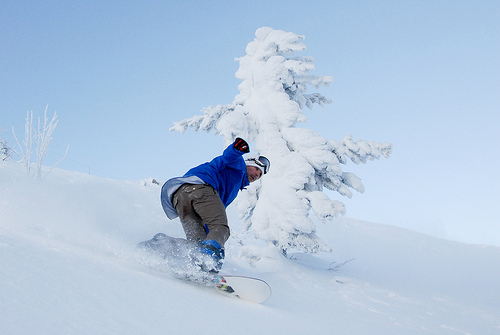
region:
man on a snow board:
[156, 129, 277, 274]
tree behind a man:
[175, 13, 397, 276]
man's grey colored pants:
[166, 178, 233, 253]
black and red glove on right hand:
[231, 133, 251, 153]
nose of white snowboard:
[212, 268, 272, 307]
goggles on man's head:
[256, 152, 270, 174]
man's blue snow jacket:
[150, 141, 253, 212]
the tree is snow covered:
[192, 14, 382, 311]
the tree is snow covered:
[10, 106, 82, 204]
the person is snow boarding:
[171, 114, 270, 310]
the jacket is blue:
[178, 126, 258, 211]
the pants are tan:
[166, 174, 256, 289]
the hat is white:
[248, 136, 280, 180]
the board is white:
[208, 243, 278, 310]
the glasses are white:
[248, 149, 280, 183]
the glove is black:
[233, 129, 249, 151]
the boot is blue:
[198, 221, 230, 277]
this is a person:
[145, 125, 308, 302]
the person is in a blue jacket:
[185, 134, 255, 204]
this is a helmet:
[246, 134, 271, 186]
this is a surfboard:
[200, 260, 297, 332]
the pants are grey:
[160, 173, 231, 244]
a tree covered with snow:
[186, 6, 379, 271]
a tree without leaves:
[12, 100, 77, 181]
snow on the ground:
[331, 275, 380, 319]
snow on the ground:
[28, 205, 105, 277]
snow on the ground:
[273, 274, 335, 317]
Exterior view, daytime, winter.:
[3, 5, 499, 332]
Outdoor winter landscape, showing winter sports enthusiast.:
[4, 5, 499, 332]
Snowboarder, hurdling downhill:
[155, 137, 270, 287]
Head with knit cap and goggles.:
[240, 155, 270, 180]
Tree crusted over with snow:
[175, 25, 380, 260]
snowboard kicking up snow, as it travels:
[150, 255, 235, 295]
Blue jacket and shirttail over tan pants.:
[166, 151, 256, 242]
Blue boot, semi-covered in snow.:
[203, 237, 220, 267]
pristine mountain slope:
[7, 165, 158, 310]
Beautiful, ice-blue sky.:
[11, 14, 168, 100]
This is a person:
[157, 131, 288, 295]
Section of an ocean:
[3, 244, 125, 334]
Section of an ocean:
[325, 102, 495, 240]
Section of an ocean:
[54, 32, 231, 135]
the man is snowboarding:
[148, 102, 295, 323]